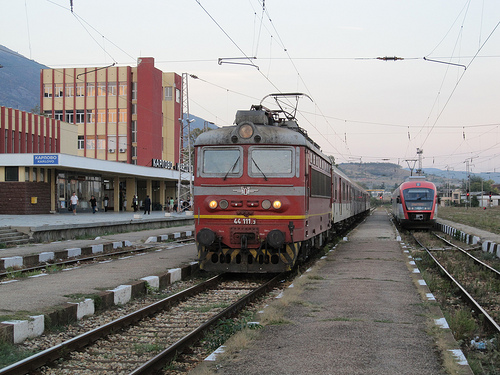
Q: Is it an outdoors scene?
A: Yes, it is outdoors.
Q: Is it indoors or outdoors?
A: It is outdoors.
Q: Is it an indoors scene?
A: No, it is outdoors.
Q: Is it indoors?
A: No, it is outdoors.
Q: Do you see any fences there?
A: No, there are no fences.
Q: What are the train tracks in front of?
A: The train tracks are in front of the hills.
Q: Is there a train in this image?
A: Yes, there is a train.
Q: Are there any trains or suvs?
A: Yes, there is a train.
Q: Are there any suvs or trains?
A: Yes, there is a train.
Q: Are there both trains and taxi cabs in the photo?
A: No, there is a train but no taxis.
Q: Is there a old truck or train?
A: Yes, there is an old train.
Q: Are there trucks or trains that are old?
A: Yes, the train is old.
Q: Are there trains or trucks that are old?
A: Yes, the train is old.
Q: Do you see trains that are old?
A: Yes, there is an old train.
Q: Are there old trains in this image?
A: Yes, there is an old train.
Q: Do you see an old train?
A: Yes, there is an old train.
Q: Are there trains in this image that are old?
A: Yes, there is a train that is old.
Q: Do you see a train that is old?
A: Yes, there is a train that is old.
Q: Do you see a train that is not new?
A: Yes, there is a old train.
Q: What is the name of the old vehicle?
A: The vehicle is a train.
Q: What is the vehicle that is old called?
A: The vehicle is a train.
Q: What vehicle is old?
A: The vehicle is a train.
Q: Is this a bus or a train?
A: This is a train.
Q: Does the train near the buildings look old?
A: Yes, the train is old.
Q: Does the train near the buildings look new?
A: No, the train is old.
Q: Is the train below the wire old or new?
A: The train is old.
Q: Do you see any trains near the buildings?
A: Yes, there is a train near the buildings.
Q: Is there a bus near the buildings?
A: No, there is a train near the buildings.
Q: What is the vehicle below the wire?
A: The vehicle is a train.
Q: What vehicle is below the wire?
A: The vehicle is a train.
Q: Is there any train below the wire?
A: Yes, there is a train below the wire.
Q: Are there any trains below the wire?
A: Yes, there is a train below the wire.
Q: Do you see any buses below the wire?
A: No, there is a train below the wire.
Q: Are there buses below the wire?
A: No, there is a train below the wire.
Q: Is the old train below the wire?
A: Yes, the train is below the wire.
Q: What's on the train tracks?
A: The train is on the railroad tracks.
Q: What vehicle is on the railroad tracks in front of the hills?
A: The vehicle is a train.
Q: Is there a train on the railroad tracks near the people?
A: Yes, there is a train on the tracks.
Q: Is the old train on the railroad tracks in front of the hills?
A: Yes, the train is on the railroad tracks.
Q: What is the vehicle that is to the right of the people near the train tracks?
A: The vehicle is a train.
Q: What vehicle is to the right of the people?
A: The vehicle is a train.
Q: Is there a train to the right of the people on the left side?
A: Yes, there is a train to the right of the people.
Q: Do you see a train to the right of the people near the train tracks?
A: Yes, there is a train to the right of the people.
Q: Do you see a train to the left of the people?
A: No, the train is to the right of the people.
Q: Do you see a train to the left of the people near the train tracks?
A: No, the train is to the right of the people.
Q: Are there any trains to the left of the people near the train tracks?
A: No, the train is to the right of the people.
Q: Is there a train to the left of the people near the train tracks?
A: No, the train is to the right of the people.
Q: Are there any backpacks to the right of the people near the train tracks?
A: No, there is a train to the right of the people.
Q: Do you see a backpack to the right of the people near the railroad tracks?
A: No, there is a train to the right of the people.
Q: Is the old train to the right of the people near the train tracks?
A: Yes, the train is to the right of the people.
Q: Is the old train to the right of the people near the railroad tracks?
A: Yes, the train is to the right of the people.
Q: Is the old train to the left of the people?
A: No, the train is to the right of the people.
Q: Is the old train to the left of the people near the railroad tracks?
A: No, the train is to the right of the people.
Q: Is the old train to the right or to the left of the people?
A: The train is to the right of the people.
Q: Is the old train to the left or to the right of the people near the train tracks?
A: The train is to the right of the people.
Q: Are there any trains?
A: Yes, there is a train.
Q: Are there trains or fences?
A: Yes, there is a train.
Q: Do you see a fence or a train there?
A: Yes, there is a train.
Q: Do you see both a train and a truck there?
A: No, there is a train but no trucks.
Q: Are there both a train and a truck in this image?
A: No, there is a train but no trucks.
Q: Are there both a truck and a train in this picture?
A: No, there is a train but no trucks.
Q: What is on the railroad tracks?
A: The train is on the railroad tracks.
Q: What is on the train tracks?
A: The train is on the railroad tracks.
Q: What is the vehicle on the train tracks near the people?
A: The vehicle is a train.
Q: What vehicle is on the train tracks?
A: The vehicle is a train.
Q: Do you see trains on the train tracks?
A: Yes, there is a train on the train tracks.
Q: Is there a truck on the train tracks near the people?
A: No, there is a train on the train tracks.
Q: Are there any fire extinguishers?
A: No, there are no fire extinguishers.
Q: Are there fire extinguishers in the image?
A: No, there are no fire extinguishers.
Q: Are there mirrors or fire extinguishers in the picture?
A: No, there are no fire extinguishers or mirrors.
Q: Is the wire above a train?
A: Yes, the wire is above a train.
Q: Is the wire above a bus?
A: No, the wire is above a train.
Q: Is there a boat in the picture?
A: No, there are no boats.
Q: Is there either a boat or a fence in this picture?
A: No, there are no boats or fences.